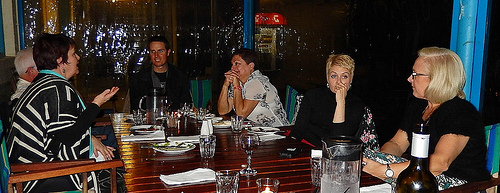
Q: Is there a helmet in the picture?
A: No, there are no helmets.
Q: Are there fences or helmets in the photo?
A: No, there are no helmets or fences.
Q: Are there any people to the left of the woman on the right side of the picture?
A: Yes, there is a person to the left of the woman.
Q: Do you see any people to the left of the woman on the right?
A: Yes, there is a person to the left of the woman.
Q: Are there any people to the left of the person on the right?
A: Yes, there is a person to the left of the woman.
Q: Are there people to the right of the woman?
A: No, the person is to the left of the woman.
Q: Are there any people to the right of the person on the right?
A: No, the person is to the left of the woman.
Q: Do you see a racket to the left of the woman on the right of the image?
A: No, there is a person to the left of the woman.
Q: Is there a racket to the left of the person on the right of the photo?
A: No, there is a person to the left of the woman.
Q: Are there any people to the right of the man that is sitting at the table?
A: Yes, there is a person to the right of the man.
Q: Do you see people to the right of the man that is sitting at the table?
A: Yes, there is a person to the right of the man.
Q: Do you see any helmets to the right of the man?
A: No, there is a person to the right of the man.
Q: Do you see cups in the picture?
A: Yes, there is a cup.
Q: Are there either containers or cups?
A: Yes, there is a cup.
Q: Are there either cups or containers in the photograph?
A: Yes, there is a cup.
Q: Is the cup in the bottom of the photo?
A: Yes, the cup is in the bottom of the image.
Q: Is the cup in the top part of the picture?
A: No, the cup is in the bottom of the image.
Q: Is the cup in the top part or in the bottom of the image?
A: The cup is in the bottom of the image.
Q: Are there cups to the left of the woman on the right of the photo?
A: Yes, there is a cup to the left of the woman.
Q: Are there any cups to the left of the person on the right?
A: Yes, there is a cup to the left of the woman.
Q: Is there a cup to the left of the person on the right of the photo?
A: Yes, there is a cup to the left of the woman.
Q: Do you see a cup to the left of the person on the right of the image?
A: Yes, there is a cup to the left of the woman.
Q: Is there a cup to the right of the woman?
A: No, the cup is to the left of the woman.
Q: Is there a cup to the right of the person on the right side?
A: No, the cup is to the left of the woman.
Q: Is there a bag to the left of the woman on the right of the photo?
A: No, there is a cup to the left of the woman.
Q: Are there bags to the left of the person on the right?
A: No, there is a cup to the left of the woman.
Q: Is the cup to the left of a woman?
A: Yes, the cup is to the left of a woman.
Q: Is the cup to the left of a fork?
A: No, the cup is to the left of a woman.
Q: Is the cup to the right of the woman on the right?
A: No, the cup is to the left of the woman.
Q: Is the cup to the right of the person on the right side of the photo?
A: No, the cup is to the left of the woman.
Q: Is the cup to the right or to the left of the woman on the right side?
A: The cup is to the left of the woman.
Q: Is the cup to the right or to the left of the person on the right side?
A: The cup is to the left of the woman.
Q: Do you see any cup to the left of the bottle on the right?
A: Yes, there is a cup to the left of the bottle.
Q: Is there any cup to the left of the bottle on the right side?
A: Yes, there is a cup to the left of the bottle.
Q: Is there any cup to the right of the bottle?
A: No, the cup is to the left of the bottle.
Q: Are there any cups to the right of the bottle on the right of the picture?
A: No, the cup is to the left of the bottle.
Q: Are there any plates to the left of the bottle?
A: No, there is a cup to the left of the bottle.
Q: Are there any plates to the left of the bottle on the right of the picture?
A: No, there is a cup to the left of the bottle.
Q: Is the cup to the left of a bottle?
A: Yes, the cup is to the left of a bottle.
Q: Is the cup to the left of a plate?
A: No, the cup is to the left of a bottle.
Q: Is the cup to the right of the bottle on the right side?
A: No, the cup is to the left of the bottle.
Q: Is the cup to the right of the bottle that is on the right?
A: No, the cup is to the left of the bottle.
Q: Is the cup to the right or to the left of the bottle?
A: The cup is to the left of the bottle.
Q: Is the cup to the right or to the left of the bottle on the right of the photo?
A: The cup is to the left of the bottle.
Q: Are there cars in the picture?
A: No, there are no cars.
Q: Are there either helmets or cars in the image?
A: No, there are no cars or helmets.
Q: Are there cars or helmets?
A: No, there are no cars or helmets.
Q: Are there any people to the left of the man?
A: Yes, there is a person to the left of the man.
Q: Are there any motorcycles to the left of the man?
A: No, there is a person to the left of the man.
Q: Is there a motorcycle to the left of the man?
A: No, there is a person to the left of the man.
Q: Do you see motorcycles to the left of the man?
A: No, there is a person to the left of the man.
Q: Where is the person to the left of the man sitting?
A: The person is sitting at the table.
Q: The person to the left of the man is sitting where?
A: The person is sitting at the table.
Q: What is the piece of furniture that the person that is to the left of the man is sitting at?
A: The piece of furniture is a table.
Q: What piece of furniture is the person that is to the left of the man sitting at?
A: The person is sitting at the table.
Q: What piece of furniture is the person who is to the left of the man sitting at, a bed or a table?
A: The person is sitting at a table.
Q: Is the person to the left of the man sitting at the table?
A: Yes, the person is sitting at the table.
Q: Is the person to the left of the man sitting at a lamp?
A: No, the person is sitting at the table.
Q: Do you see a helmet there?
A: No, there are no helmets.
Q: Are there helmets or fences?
A: No, there are no helmets or fences.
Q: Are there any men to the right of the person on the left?
A: Yes, there is a man to the right of the person.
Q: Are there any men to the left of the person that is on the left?
A: No, the man is to the right of the person.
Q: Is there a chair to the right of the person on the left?
A: No, there is a man to the right of the person.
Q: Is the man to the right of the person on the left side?
A: Yes, the man is to the right of the person.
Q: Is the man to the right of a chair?
A: No, the man is to the right of the person.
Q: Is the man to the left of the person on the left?
A: No, the man is to the right of the person.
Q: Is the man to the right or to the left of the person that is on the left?
A: The man is to the right of the person.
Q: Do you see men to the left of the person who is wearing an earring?
A: Yes, there is a man to the left of the person.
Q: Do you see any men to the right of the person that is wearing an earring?
A: No, the man is to the left of the person.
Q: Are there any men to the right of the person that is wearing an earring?
A: No, the man is to the left of the person.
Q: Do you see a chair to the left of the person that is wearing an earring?
A: No, there is a man to the left of the person.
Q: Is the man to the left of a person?
A: Yes, the man is to the left of a person.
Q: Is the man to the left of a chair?
A: No, the man is to the left of a person.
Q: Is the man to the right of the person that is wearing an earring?
A: No, the man is to the left of the person.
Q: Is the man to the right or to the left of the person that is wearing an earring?
A: The man is to the left of the person.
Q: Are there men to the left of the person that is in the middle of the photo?
A: Yes, there is a man to the left of the person.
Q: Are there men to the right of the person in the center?
A: No, the man is to the left of the person.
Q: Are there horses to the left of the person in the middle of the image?
A: No, there is a man to the left of the person.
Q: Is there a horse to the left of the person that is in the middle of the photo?
A: No, there is a man to the left of the person.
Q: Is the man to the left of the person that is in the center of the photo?
A: Yes, the man is to the left of the person.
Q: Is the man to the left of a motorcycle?
A: No, the man is to the left of the person.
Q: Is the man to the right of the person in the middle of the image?
A: No, the man is to the left of the person.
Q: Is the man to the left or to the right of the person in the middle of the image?
A: The man is to the left of the person.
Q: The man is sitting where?
A: The man is sitting at the table.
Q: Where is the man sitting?
A: The man is sitting at the table.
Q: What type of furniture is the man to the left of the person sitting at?
A: The man is sitting at the table.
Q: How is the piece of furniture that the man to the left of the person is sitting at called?
A: The piece of furniture is a table.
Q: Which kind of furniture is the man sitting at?
A: The man is sitting at the table.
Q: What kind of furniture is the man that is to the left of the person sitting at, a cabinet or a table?
A: The man is sitting at a table.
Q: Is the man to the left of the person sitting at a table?
A: Yes, the man is sitting at a table.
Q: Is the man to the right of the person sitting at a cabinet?
A: No, the man is sitting at a table.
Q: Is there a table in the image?
A: Yes, there is a table.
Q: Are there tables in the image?
A: Yes, there is a table.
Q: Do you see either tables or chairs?
A: Yes, there is a table.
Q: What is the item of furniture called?
A: The piece of furniture is a table.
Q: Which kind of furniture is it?
A: The piece of furniture is a table.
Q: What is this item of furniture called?
A: This is a table.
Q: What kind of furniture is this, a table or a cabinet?
A: This is a table.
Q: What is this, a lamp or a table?
A: This is a table.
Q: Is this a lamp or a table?
A: This is a table.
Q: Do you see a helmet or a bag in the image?
A: No, there are no helmets or bags.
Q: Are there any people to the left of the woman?
A: Yes, there is a person to the left of the woman.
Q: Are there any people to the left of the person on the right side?
A: Yes, there is a person to the left of the woman.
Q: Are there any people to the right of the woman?
A: No, the person is to the left of the woman.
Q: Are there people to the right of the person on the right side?
A: No, the person is to the left of the woman.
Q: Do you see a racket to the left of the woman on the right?
A: No, there is a person to the left of the woman.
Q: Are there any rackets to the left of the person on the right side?
A: No, there is a person to the left of the woman.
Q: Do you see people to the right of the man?
A: Yes, there is a person to the right of the man.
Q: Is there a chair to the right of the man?
A: No, there is a person to the right of the man.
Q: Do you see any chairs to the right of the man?
A: No, there is a person to the right of the man.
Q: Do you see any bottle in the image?
A: Yes, there is a bottle.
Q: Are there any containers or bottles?
A: Yes, there is a bottle.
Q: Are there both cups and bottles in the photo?
A: Yes, there are both a bottle and a cup.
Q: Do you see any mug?
A: No, there are no mugs.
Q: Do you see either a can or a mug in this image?
A: No, there are no mugs or cans.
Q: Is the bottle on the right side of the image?
A: Yes, the bottle is on the right of the image.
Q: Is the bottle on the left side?
A: No, the bottle is on the right of the image.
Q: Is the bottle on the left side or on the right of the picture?
A: The bottle is on the right of the image.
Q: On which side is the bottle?
A: The bottle is on the right of the image.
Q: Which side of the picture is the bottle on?
A: The bottle is on the right of the image.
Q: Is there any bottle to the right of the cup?
A: Yes, there is a bottle to the right of the cup.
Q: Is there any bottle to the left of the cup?
A: No, the bottle is to the right of the cup.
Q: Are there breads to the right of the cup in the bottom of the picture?
A: No, there is a bottle to the right of the cup.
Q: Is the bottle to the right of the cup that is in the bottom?
A: Yes, the bottle is to the right of the cup.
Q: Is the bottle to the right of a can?
A: No, the bottle is to the right of the cup.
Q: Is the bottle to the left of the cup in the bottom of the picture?
A: No, the bottle is to the right of the cup.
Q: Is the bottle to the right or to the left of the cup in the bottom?
A: The bottle is to the right of the cup.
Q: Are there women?
A: Yes, there is a woman.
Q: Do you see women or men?
A: Yes, there is a woman.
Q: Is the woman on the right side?
A: Yes, the woman is on the right of the image.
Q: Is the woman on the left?
A: No, the woman is on the right of the image.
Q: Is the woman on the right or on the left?
A: The woman is on the right of the image.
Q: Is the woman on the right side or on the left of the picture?
A: The woman is on the right of the image.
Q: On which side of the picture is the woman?
A: The woman is on the right of the image.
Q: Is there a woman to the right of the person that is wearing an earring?
A: Yes, there is a woman to the right of the person.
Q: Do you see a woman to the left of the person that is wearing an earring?
A: No, the woman is to the right of the person.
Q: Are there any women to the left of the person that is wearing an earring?
A: No, the woman is to the right of the person.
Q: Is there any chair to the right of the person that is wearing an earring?
A: No, there is a woman to the right of the person.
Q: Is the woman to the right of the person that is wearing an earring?
A: Yes, the woman is to the right of the person.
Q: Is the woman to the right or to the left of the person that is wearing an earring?
A: The woman is to the right of the person.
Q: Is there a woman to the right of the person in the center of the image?
A: Yes, there is a woman to the right of the person.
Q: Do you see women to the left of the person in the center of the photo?
A: No, the woman is to the right of the person.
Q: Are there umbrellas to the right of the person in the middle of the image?
A: No, there is a woman to the right of the person.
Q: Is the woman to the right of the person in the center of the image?
A: Yes, the woman is to the right of the person.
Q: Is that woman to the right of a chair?
A: No, the woman is to the right of the person.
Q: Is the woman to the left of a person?
A: No, the woman is to the right of a person.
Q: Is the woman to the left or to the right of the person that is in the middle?
A: The woman is to the right of the person.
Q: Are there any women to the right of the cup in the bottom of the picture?
A: Yes, there is a woman to the right of the cup.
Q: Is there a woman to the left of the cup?
A: No, the woman is to the right of the cup.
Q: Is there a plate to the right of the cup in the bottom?
A: No, there is a woman to the right of the cup.